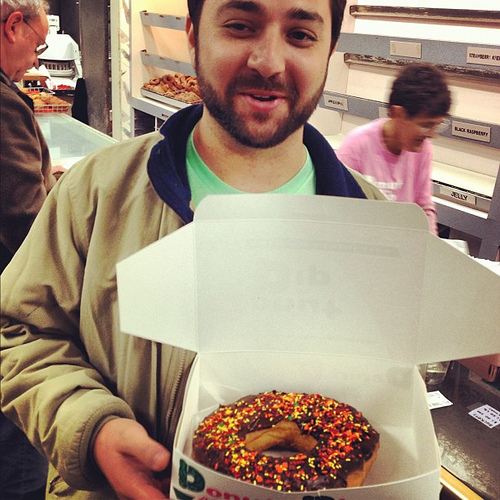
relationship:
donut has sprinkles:
[212, 388, 352, 500] [281, 389, 325, 423]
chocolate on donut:
[200, 448, 234, 473] [212, 388, 352, 500]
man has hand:
[17, 0, 438, 481] [91, 408, 186, 492]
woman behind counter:
[347, 60, 459, 216] [427, 369, 497, 478]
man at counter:
[6, 13, 62, 224] [427, 369, 497, 478]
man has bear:
[17, 0, 438, 481] [222, 107, 291, 162]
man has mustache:
[17, 0, 438, 481] [244, 66, 302, 109]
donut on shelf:
[145, 66, 179, 99] [150, 10, 206, 113]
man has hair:
[17, 0, 438, 481] [190, 1, 212, 38]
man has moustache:
[17, 0, 438, 481] [240, 63, 288, 92]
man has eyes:
[17, 0, 438, 481] [231, 10, 332, 71]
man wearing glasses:
[6, 13, 62, 224] [19, 19, 67, 67]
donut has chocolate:
[212, 388, 352, 500] [200, 448, 234, 473]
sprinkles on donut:
[281, 389, 325, 423] [212, 388, 352, 500]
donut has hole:
[212, 388, 352, 500] [253, 413, 318, 457]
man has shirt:
[17, 0, 438, 481] [182, 133, 320, 227]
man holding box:
[17, 0, 438, 481] [128, 189, 487, 499]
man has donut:
[17, 0, 438, 481] [212, 388, 352, 500]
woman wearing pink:
[347, 60, 459, 216] [364, 133, 433, 203]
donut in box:
[212, 388, 352, 500] [128, 189, 487, 499]